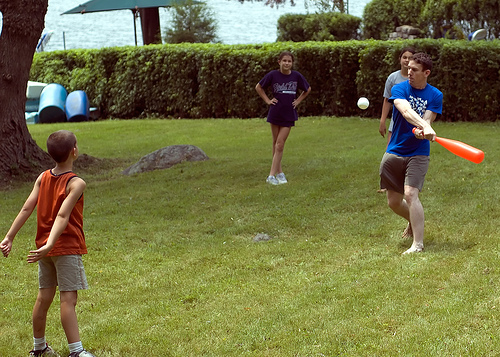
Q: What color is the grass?
A: Green.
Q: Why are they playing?
A: For fun.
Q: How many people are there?
A: Four.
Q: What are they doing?
A: Playing.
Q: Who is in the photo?
A: Four people.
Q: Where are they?
A: In grass.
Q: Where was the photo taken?
A: In a front yard.